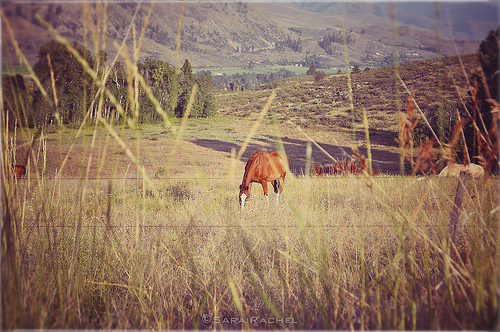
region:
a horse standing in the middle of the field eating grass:
[231, 144, 286, 211]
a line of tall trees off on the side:
[9, 43, 216, 131]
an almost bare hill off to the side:
[1, 0, 427, 75]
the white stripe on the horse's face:
[238, 188, 248, 207]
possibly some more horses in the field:
[307, 156, 375, 176]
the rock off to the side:
[436, 156, 482, 179]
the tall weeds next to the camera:
[3, 120, 497, 324]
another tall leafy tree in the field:
[471, 27, 498, 163]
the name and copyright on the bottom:
[195, 312, 304, 325]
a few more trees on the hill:
[313, 23, 348, 53]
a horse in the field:
[226, 135, 328, 244]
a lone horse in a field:
[216, 125, 357, 260]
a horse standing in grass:
[207, 113, 307, 268]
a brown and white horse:
[199, 140, 335, 232]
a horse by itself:
[208, 121, 328, 235]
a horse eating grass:
[219, 118, 363, 248]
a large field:
[41, 133, 476, 320]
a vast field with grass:
[61, 139, 493, 316]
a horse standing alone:
[201, 138, 326, 286]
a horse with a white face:
[212, 137, 352, 329]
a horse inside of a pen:
[228, 145, 312, 216]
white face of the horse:
[236, 191, 247, 205]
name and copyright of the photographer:
[191, 309, 307, 328]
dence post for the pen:
[443, 163, 480, 283]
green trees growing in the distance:
[14, 48, 218, 128]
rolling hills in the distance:
[36, 0, 446, 70]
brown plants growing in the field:
[318, 152, 385, 184]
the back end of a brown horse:
[0, 155, 40, 184]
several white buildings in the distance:
[276, 31, 421, 71]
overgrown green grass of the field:
[99, 188, 199, 247]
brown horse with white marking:
[204, 133, 320, 228]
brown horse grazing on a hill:
[207, 138, 305, 228]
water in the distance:
[187, 129, 460, 187]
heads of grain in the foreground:
[12, 10, 184, 255]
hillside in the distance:
[0, 3, 497, 63]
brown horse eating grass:
[199, 140, 304, 237]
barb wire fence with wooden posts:
[29, 158, 491, 290]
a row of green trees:
[3, 46, 231, 129]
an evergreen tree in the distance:
[177, 55, 194, 121]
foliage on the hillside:
[264, 57, 494, 149]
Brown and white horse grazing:
[238, 150, 286, 212]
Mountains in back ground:
[10, 5, 472, 87]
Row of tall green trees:
[1, 41, 221, 123]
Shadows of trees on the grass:
[191, 128, 440, 174]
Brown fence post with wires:
[435, 168, 470, 259]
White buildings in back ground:
[367, 45, 428, 58]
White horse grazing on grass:
[432, 162, 485, 177]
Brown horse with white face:
[238, 183, 249, 208]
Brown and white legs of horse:
[260, 180, 285, 206]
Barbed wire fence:
[2, 163, 494, 266]